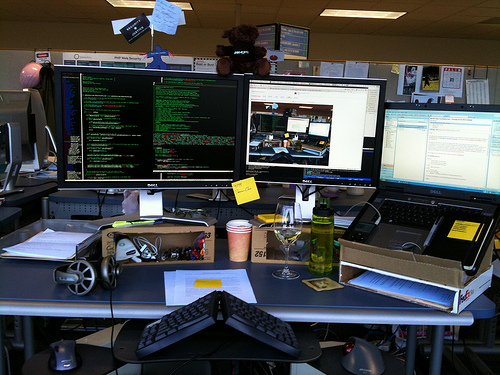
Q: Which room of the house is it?
A: It is an office.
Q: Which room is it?
A: It is an office.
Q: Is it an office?
A: Yes, it is an office.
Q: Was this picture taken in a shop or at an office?
A: It was taken at an office.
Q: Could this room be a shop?
A: No, it is an office.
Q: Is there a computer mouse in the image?
A: Yes, there is a computer mouse.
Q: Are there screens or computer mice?
A: Yes, there is a computer mouse.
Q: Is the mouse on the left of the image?
A: Yes, the mouse is on the left of the image.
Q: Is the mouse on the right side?
A: No, the mouse is on the left of the image.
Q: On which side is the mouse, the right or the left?
A: The mouse is on the left of the image.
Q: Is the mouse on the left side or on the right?
A: The mouse is on the left of the image.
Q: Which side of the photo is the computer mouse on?
A: The computer mouse is on the left of the image.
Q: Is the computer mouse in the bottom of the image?
A: Yes, the computer mouse is in the bottom of the image.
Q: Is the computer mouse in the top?
A: No, the computer mouse is in the bottom of the image.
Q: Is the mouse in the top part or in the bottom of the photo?
A: The mouse is in the bottom of the image.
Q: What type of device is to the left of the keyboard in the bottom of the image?
A: The device is a computer mouse.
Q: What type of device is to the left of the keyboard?
A: The device is a computer mouse.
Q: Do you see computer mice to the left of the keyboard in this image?
A: Yes, there is a computer mouse to the left of the keyboard.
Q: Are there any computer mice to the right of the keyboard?
A: No, the computer mouse is to the left of the keyboard.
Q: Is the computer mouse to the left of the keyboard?
A: Yes, the computer mouse is to the left of the keyboard.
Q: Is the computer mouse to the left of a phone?
A: No, the computer mouse is to the left of the keyboard.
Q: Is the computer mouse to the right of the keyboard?
A: No, the computer mouse is to the left of the keyboard.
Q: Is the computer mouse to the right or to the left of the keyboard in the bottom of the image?
A: The computer mouse is to the left of the keyboard.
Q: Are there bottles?
A: Yes, there is a bottle.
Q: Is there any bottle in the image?
A: Yes, there is a bottle.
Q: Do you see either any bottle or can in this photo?
A: Yes, there is a bottle.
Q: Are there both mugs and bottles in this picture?
A: No, there is a bottle but no mugs.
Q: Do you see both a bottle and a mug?
A: No, there is a bottle but no mugs.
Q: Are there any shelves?
A: No, there are no shelves.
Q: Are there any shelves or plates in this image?
A: No, there are no shelves or plates.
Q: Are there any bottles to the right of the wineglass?
A: Yes, there is a bottle to the right of the wineglass.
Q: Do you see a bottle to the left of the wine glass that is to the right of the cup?
A: No, the bottle is to the right of the wineglass.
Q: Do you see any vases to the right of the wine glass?
A: No, there is a bottle to the right of the wine glass.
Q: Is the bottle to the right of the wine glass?
A: Yes, the bottle is to the right of the wine glass.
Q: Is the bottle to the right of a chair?
A: No, the bottle is to the right of the wine glass.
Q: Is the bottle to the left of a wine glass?
A: No, the bottle is to the right of a wine glass.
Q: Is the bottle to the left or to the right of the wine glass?
A: The bottle is to the right of the wine glass.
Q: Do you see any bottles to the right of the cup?
A: Yes, there is a bottle to the right of the cup.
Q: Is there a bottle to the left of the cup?
A: No, the bottle is to the right of the cup.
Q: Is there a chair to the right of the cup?
A: No, there is a bottle to the right of the cup.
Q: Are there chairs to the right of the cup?
A: No, there is a bottle to the right of the cup.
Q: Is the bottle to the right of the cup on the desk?
A: Yes, the bottle is to the right of the cup.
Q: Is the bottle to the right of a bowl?
A: No, the bottle is to the right of the cup.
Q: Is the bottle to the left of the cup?
A: No, the bottle is to the right of the cup.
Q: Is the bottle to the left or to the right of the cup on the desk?
A: The bottle is to the right of the cup.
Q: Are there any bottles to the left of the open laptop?
A: Yes, there is a bottle to the left of the laptop.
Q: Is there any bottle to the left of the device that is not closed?
A: Yes, there is a bottle to the left of the laptop.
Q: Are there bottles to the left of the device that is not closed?
A: Yes, there is a bottle to the left of the laptop.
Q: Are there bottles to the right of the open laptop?
A: No, the bottle is to the left of the laptop.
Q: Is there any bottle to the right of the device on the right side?
A: No, the bottle is to the left of the laptop.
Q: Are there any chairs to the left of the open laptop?
A: No, there is a bottle to the left of the laptop.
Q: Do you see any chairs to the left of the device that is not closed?
A: No, there is a bottle to the left of the laptop.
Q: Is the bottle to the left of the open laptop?
A: Yes, the bottle is to the left of the laptop.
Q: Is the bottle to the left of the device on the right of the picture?
A: Yes, the bottle is to the left of the laptop.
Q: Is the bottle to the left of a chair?
A: No, the bottle is to the left of the laptop.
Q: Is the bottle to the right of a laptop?
A: No, the bottle is to the left of a laptop.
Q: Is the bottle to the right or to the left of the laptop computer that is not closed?
A: The bottle is to the left of the laptop.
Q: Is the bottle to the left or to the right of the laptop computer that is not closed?
A: The bottle is to the left of the laptop.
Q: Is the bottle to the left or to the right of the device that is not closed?
A: The bottle is to the left of the laptop.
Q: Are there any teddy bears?
A: Yes, there is a teddy bear.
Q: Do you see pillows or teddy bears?
A: Yes, there is a teddy bear.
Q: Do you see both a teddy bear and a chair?
A: No, there is a teddy bear but no chairs.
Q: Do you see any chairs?
A: No, there are no chairs.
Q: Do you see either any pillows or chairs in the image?
A: No, there are no chairs or pillows.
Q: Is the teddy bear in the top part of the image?
A: Yes, the teddy bear is in the top of the image.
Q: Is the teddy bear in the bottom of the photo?
A: No, the teddy bear is in the top of the image.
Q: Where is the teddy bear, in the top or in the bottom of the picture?
A: The teddy bear is in the top of the image.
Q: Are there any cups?
A: Yes, there is a cup.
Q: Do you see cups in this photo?
A: Yes, there is a cup.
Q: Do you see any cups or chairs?
A: Yes, there is a cup.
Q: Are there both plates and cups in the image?
A: No, there is a cup but no plates.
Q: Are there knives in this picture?
A: No, there are no knives.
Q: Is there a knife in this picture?
A: No, there are no knives.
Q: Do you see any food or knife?
A: No, there are no knives or food.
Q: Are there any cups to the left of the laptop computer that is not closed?
A: Yes, there is a cup to the left of the laptop.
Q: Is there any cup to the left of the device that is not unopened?
A: Yes, there is a cup to the left of the laptop.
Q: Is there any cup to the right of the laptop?
A: No, the cup is to the left of the laptop.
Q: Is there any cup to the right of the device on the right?
A: No, the cup is to the left of the laptop.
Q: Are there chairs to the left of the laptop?
A: No, there is a cup to the left of the laptop.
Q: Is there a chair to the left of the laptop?
A: No, there is a cup to the left of the laptop.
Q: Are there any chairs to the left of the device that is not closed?
A: No, there is a cup to the left of the laptop.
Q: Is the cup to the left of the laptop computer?
A: Yes, the cup is to the left of the laptop computer.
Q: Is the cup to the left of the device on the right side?
A: Yes, the cup is to the left of the laptop computer.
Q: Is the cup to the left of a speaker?
A: No, the cup is to the left of the laptop computer.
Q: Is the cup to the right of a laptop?
A: No, the cup is to the left of a laptop.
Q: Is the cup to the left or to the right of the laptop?
A: The cup is to the left of the laptop.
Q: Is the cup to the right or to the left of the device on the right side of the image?
A: The cup is to the left of the laptop.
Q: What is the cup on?
A: The cup is on the desk.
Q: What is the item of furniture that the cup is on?
A: The piece of furniture is a desk.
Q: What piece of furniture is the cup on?
A: The cup is on the desk.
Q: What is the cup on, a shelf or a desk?
A: The cup is on a desk.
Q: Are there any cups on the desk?
A: Yes, there is a cup on the desk.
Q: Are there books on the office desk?
A: No, there is a cup on the desk.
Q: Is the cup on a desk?
A: Yes, the cup is on a desk.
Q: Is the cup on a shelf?
A: No, the cup is on a desk.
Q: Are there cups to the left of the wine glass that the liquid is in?
A: Yes, there is a cup to the left of the wine glass.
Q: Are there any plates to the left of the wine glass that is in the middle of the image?
A: No, there is a cup to the left of the wine glass.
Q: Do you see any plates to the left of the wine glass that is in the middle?
A: No, there is a cup to the left of the wine glass.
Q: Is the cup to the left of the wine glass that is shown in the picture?
A: Yes, the cup is to the left of the wine glass.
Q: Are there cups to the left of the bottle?
A: Yes, there is a cup to the left of the bottle.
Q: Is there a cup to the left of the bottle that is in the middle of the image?
A: Yes, there is a cup to the left of the bottle.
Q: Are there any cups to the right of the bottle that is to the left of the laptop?
A: No, the cup is to the left of the bottle.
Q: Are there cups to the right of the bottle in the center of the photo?
A: No, the cup is to the left of the bottle.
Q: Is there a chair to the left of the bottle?
A: No, there is a cup to the left of the bottle.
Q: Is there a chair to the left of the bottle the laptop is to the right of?
A: No, there is a cup to the left of the bottle.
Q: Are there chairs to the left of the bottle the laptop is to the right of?
A: No, there is a cup to the left of the bottle.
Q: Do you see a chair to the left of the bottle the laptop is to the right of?
A: No, there is a cup to the left of the bottle.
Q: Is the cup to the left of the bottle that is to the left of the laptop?
A: Yes, the cup is to the left of the bottle.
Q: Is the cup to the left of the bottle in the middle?
A: Yes, the cup is to the left of the bottle.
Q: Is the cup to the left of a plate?
A: No, the cup is to the left of the bottle.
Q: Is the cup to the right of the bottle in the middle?
A: No, the cup is to the left of the bottle.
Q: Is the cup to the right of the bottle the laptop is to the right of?
A: No, the cup is to the left of the bottle.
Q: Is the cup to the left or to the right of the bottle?
A: The cup is to the left of the bottle.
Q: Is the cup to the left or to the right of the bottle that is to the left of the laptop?
A: The cup is to the left of the bottle.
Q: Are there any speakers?
A: No, there are no speakers.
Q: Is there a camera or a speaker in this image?
A: No, there are no speakers or cameras.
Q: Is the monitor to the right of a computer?
A: Yes, the monitor is to the right of a computer.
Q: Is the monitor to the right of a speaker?
A: No, the monitor is to the right of a computer.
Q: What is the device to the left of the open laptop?
A: The device is a monitor.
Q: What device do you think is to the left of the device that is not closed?
A: The device is a monitor.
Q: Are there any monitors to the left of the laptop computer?
A: Yes, there is a monitor to the left of the laptop computer.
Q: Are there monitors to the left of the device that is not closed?
A: Yes, there is a monitor to the left of the laptop computer.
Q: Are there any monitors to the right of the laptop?
A: No, the monitor is to the left of the laptop.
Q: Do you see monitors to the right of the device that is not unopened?
A: No, the monitor is to the left of the laptop.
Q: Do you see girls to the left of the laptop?
A: No, there is a monitor to the left of the laptop.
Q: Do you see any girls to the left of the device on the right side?
A: No, there is a monitor to the left of the laptop.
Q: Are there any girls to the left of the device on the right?
A: No, there is a monitor to the left of the laptop.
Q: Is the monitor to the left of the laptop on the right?
A: Yes, the monitor is to the left of the laptop.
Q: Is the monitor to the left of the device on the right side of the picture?
A: Yes, the monitor is to the left of the laptop.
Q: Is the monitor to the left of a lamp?
A: No, the monitor is to the left of the laptop.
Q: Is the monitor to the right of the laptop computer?
A: No, the monitor is to the left of the laptop computer.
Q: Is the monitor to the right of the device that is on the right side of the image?
A: No, the monitor is to the left of the laptop computer.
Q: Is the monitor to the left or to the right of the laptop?
A: The monitor is to the left of the laptop.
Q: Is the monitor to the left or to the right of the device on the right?
A: The monitor is to the left of the laptop.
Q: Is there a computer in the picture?
A: Yes, there is a computer.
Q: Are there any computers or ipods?
A: Yes, there is a computer.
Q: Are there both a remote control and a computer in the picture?
A: No, there is a computer but no remote controls.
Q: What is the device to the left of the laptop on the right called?
A: The device is a computer.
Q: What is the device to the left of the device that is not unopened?
A: The device is a computer.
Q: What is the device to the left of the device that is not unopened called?
A: The device is a computer.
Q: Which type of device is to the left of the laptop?
A: The device is a computer.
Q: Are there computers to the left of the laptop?
A: Yes, there is a computer to the left of the laptop.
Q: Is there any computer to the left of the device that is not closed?
A: Yes, there is a computer to the left of the laptop.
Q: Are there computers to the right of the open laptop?
A: No, the computer is to the left of the laptop.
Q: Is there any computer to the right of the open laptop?
A: No, the computer is to the left of the laptop.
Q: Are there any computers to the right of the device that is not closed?
A: No, the computer is to the left of the laptop.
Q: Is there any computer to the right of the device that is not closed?
A: No, the computer is to the left of the laptop.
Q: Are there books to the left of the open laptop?
A: No, there is a computer to the left of the laptop.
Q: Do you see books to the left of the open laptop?
A: No, there is a computer to the left of the laptop.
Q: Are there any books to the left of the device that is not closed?
A: No, there is a computer to the left of the laptop.